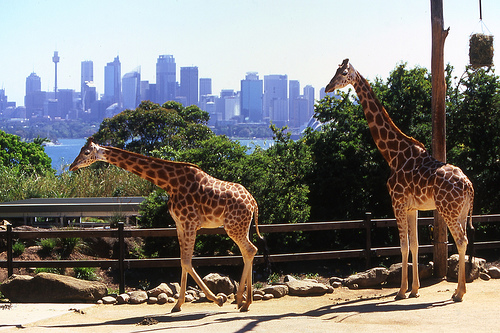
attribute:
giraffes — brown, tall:
[68, 57, 478, 310]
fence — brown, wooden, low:
[3, 208, 499, 289]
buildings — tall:
[3, 50, 321, 134]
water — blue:
[32, 138, 299, 169]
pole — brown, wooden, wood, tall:
[431, 6, 450, 275]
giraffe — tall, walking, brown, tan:
[326, 61, 474, 306]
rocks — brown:
[1, 254, 500, 305]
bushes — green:
[135, 60, 500, 250]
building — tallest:
[155, 55, 177, 100]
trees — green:
[0, 99, 258, 176]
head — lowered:
[64, 136, 108, 168]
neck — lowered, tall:
[102, 145, 174, 189]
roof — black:
[156, 54, 176, 62]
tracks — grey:
[1, 191, 142, 223]